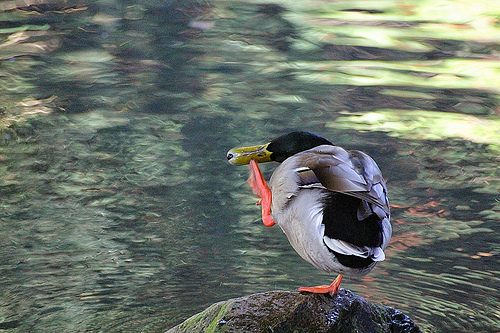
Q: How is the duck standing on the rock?
A: On one foot.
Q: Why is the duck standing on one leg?
A: To use the other foot to scratch the head.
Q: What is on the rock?
A: A black and grey duck.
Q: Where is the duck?
A: Standing on a rock by the river.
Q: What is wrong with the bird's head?
A: Itching.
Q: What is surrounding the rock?
A: Water.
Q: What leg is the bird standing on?
A: Right.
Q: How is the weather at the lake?
A: Sunshine.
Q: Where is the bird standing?
A: Rock.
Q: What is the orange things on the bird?
A: Feet.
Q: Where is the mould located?
A: Stone.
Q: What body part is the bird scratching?
A: Beak.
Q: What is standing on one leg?
A: Bird.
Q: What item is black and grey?
A: Feathers.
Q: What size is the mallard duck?
A: Small.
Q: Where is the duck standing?
A: Rock.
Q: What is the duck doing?
A: Cleaning itself.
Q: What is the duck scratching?
A: His bill.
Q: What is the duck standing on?
A: A big rock.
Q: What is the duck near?
A: Water.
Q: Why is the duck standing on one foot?
A: Cleaning his face.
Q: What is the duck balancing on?
A: A rock.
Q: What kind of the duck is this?
A: A mallard.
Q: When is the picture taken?
A: Daytime.